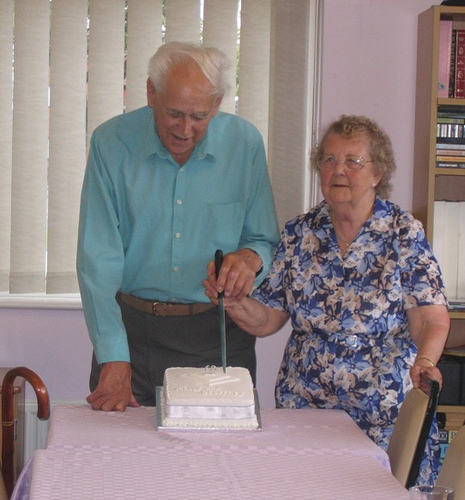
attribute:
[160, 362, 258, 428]
cake — special, celebration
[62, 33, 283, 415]
man — elderly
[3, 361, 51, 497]
walking cane — wooden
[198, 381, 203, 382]
frosting — white 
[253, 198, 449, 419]
dress — flowery 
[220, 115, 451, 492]
woman — elderly, white , tan 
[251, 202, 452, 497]
dress — blue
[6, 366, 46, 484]
cane — wood , leaning 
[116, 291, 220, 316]
belt — brown 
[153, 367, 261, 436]
cake — white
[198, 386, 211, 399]
frosting — vanilla 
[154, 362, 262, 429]
cake — decorated , Vanilla 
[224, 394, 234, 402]
icing — White 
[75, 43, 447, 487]
couple — Elderly 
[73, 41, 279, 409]
man — elderly, teal 